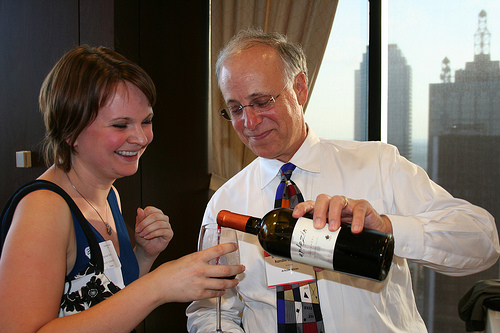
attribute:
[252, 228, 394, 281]
wine — red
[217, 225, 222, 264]
wine — pouring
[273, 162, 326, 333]
tie — multi-colored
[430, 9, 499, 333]
building — in the distance